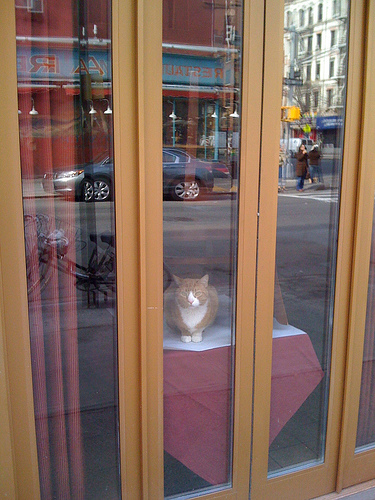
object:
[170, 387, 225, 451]
cloth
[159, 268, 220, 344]
cat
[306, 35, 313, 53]
window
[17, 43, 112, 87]
reflection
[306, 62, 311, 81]
window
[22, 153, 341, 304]
road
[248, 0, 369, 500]
door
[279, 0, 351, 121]
building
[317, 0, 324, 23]
window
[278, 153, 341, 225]
cross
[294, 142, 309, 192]
person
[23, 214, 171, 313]
reflection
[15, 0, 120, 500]
glass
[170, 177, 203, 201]
rim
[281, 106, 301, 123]
sign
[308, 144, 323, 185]
person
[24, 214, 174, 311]
bicycle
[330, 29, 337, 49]
window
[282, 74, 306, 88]
reflection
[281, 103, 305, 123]
reflection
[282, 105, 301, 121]
traffic light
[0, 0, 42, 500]
frame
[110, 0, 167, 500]
frame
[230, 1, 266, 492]
frame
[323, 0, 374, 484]
frame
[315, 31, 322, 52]
window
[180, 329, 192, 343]
legs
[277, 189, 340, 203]
crosswalk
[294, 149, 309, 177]
jacket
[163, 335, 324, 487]
table cloth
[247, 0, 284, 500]
frame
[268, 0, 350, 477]
glass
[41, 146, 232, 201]
car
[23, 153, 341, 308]
street